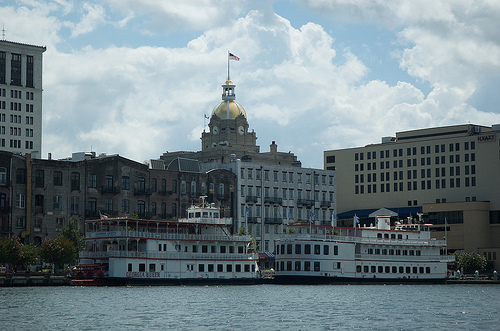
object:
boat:
[66, 190, 281, 288]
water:
[0, 277, 497, 330]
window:
[353, 152, 359, 162]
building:
[320, 120, 500, 277]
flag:
[221, 48, 242, 79]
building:
[156, 75, 309, 171]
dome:
[208, 78, 249, 123]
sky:
[1, 0, 500, 167]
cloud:
[53, 24, 195, 118]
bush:
[447, 246, 491, 277]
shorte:
[452, 265, 498, 284]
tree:
[0, 234, 43, 276]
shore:
[5, 268, 90, 289]